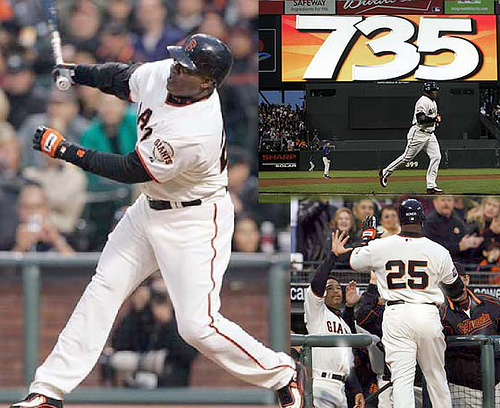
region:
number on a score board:
[278, 8, 491, 83]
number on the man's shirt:
[382, 255, 430, 290]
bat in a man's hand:
[38, 1, 76, 96]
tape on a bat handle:
[46, 29, 69, 79]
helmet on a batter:
[167, 28, 234, 87]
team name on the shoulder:
[142, 138, 184, 170]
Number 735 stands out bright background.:
[272, 8, 499, 88]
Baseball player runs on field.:
[379, 78, 452, 196]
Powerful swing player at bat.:
[38, 13, 251, 233]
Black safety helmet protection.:
[156, 5, 237, 115]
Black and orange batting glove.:
[22, 120, 75, 168]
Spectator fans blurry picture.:
[9, 2, 266, 247]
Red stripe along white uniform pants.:
[197, 178, 280, 406]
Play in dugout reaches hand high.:
[303, 222, 358, 406]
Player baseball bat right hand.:
[33, 1, 85, 111]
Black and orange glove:
[31, 126, 68, 160]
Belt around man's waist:
[139, 197, 200, 208]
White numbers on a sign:
[287, 12, 484, 81]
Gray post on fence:
[0, 247, 103, 262]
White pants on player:
[36, 194, 291, 388]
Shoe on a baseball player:
[270, 360, 304, 404]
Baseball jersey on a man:
[352, 233, 450, 302]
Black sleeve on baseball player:
[65, 144, 148, 188]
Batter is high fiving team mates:
[296, 197, 498, 404]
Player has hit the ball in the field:
[2, 5, 304, 405]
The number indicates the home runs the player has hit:
[287, 4, 499, 82]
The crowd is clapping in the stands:
[307, 198, 492, 271]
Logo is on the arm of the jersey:
[138, 131, 185, 183]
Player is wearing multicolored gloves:
[15, 113, 73, 180]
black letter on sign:
[296, 0, 303, 7]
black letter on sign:
[301, 0, 308, 7]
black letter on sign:
[305, 0, 311, 9]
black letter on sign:
[314, 0, 323, 5]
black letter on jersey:
[324, 320, 333, 332]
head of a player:
[126, 15, 251, 125]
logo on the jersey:
[145, 130, 194, 171]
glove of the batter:
[21, 107, 93, 170]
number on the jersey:
[369, 238, 444, 299]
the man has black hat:
[156, 13, 241, 110]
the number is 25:
[369, 250, 438, 297]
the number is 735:
[292, 11, 477, 89]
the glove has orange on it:
[24, 117, 77, 163]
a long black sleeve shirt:
[66, 133, 188, 201]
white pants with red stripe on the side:
[26, 183, 298, 405]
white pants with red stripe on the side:
[382, 124, 442, 193]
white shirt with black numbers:
[350, 231, 458, 299]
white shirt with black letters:
[128, 57, 231, 203]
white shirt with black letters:
[411, 96, 437, 133]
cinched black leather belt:
[139, 185, 230, 212]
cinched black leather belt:
[383, 298, 441, 309]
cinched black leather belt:
[309, 368, 348, 383]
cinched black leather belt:
[411, 120, 434, 135]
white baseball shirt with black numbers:
[350, 233, 457, 303]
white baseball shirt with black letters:
[302, 287, 357, 374]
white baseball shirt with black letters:
[126, 55, 229, 203]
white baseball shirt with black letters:
[411, 94, 440, 133]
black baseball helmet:
[165, 33, 232, 87]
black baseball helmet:
[397, 198, 427, 223]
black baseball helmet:
[420, 80, 439, 90]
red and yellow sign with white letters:
[280, 10, 498, 80]